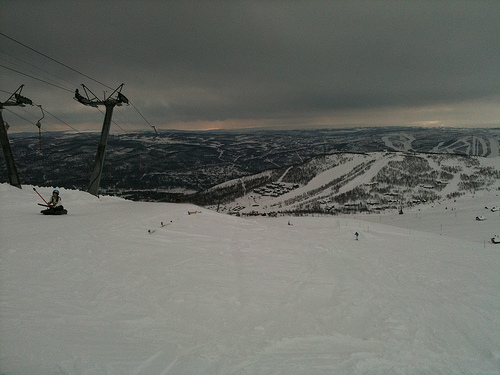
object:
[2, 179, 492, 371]
snow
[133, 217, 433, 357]
tracks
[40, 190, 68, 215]
person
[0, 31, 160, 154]
lines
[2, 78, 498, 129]
clouds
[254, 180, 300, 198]
cars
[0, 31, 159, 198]
ski lift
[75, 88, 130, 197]
pole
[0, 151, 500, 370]
mountain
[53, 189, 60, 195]
helmet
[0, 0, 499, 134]
sky